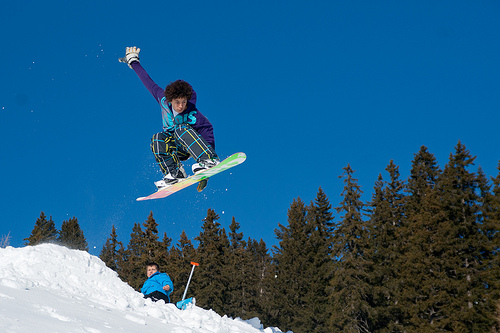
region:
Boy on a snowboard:
[138, 151, 245, 205]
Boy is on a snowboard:
[134, 142, 249, 210]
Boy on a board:
[131, 150, 249, 205]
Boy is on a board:
[135, 150, 249, 203]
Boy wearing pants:
[147, 122, 222, 174]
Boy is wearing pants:
[147, 127, 216, 176]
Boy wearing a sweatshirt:
[130, 61, 220, 145]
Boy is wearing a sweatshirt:
[127, 60, 220, 152]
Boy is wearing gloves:
[117, 39, 145, 69]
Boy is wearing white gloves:
[108, 40, 140, 66]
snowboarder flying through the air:
[115, 42, 246, 198]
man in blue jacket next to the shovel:
[140, 256, 200, 306]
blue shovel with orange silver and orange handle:
[172, 257, 192, 302]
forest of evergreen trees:
[20, 146, 486, 327]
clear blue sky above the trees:
[0, 0, 495, 245]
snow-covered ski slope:
[0, 245, 265, 330]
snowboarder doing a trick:
[116, 45, 242, 196]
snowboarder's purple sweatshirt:
[130, 58, 213, 148]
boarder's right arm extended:
[117, 43, 164, 100]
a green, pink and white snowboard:
[131, 150, 246, 201]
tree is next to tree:
[29, 211, 51, 252]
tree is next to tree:
[31, 213, 61, 242]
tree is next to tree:
[55, 217, 89, 251]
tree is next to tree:
[93, 222, 122, 276]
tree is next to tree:
[124, 224, 155, 297]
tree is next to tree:
[143, 210, 166, 302]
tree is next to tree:
[313, 161, 384, 331]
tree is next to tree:
[248, 193, 335, 330]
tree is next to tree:
[310, 189, 340, 277]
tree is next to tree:
[221, 218, 257, 318]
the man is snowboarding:
[100, 26, 259, 201]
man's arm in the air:
[115, 36, 165, 105]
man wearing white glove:
[115, 34, 148, 71]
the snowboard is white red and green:
[127, 143, 254, 203]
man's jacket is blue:
[138, 265, 176, 301]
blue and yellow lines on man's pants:
[132, 126, 217, 179]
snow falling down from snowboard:
[194, 169, 236, 229]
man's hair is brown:
[159, 75, 200, 105]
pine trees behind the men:
[21, 128, 499, 329]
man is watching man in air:
[134, 244, 185, 318]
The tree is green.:
[26, 201, 62, 250]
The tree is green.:
[54, 209, 89, 258]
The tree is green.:
[96, 218, 129, 271]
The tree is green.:
[121, 213, 144, 288]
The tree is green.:
[139, 210, 171, 299]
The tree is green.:
[168, 225, 203, 310]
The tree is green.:
[193, 204, 237, 316]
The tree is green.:
[227, 233, 262, 328]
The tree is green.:
[258, 189, 329, 331]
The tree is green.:
[315, 150, 387, 332]